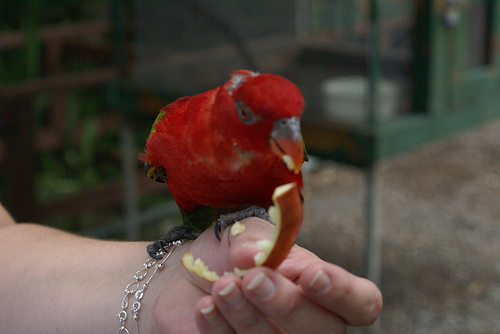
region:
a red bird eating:
[141, 54, 312, 299]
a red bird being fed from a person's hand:
[0, 51, 388, 326]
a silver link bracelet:
[119, 234, 178, 329]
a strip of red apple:
[170, 184, 308, 299]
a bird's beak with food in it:
[261, 111, 312, 181]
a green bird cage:
[109, 4, 499, 309]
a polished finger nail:
[239, 270, 278, 305]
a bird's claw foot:
[141, 215, 198, 264]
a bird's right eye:
[226, 96, 258, 131]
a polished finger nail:
[304, 264, 336, 294]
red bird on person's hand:
[160, 46, 332, 253]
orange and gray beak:
[271, 118, 312, 168]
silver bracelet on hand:
[112, 233, 183, 332]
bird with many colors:
[145, 85, 312, 213]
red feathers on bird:
[171, 100, 231, 177]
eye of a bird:
[228, 96, 262, 138]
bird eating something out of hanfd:
[138, 78, 363, 310]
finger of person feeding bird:
[292, 259, 340, 308]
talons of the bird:
[150, 207, 257, 260]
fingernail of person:
[240, 263, 293, 311]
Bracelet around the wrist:
[115, 236, 179, 332]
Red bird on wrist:
[140, 65, 308, 256]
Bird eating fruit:
[139, 65, 308, 332]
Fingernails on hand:
[143, 213, 383, 332]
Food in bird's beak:
[143, 67, 310, 254]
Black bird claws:
[145, 197, 277, 261]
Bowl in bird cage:
[311, 0, 498, 332]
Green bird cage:
[118, 1, 494, 331]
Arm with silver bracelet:
[1, 203, 396, 332]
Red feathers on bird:
[139, 67, 314, 252]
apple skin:
[190, 195, 329, 288]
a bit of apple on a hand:
[216, 218, 248, 235]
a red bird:
[149, 72, 336, 212]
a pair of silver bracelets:
[105, 244, 181, 316]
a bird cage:
[136, 22, 488, 130]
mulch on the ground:
[352, 165, 488, 261]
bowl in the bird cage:
[321, 63, 394, 115]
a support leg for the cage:
[361, 167, 405, 331]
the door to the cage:
[419, 12, 496, 104]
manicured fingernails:
[188, 250, 335, 314]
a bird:
[137, 65, 310, 251]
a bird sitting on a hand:
[0, 67, 383, 332]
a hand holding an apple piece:
[151, 185, 384, 332]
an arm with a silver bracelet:
[117, 233, 187, 331]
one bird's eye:
[230, 96, 259, 125]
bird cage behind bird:
[105, 2, 499, 332]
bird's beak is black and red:
[267, 113, 307, 175]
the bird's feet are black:
[145, 202, 277, 262]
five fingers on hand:
[149, 211, 381, 332]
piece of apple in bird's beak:
[268, 114, 308, 175]